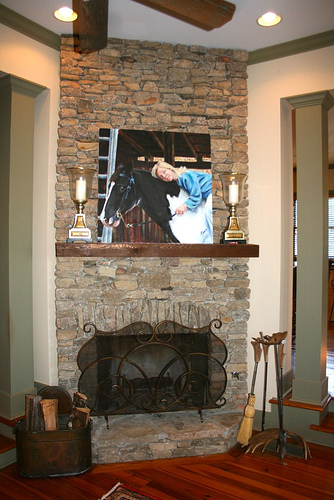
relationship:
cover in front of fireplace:
[75, 318, 229, 424] [55, 34, 260, 467]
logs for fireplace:
[24, 393, 91, 431] [55, 34, 260, 467]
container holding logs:
[13, 415, 91, 478] [24, 393, 91, 431]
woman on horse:
[151, 159, 216, 237] [98, 157, 212, 245]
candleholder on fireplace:
[221, 173, 246, 245] [55, 34, 260, 467]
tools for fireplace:
[235, 331, 313, 460] [55, 34, 260, 467]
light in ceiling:
[258, 11, 281, 27] [3, 1, 332, 55]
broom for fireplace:
[237, 342, 260, 448] [55, 34, 260, 467]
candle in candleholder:
[229, 182, 241, 205] [221, 173, 246, 245]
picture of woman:
[98, 128, 211, 246] [151, 159, 216, 237]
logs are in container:
[24, 393, 91, 431] [13, 415, 91, 478]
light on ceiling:
[52, 7, 79, 25] [3, 1, 332, 55]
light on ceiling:
[258, 11, 281, 27] [3, 1, 332, 55]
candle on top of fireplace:
[229, 182, 241, 205] [55, 34, 260, 467]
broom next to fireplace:
[237, 342, 260, 448] [55, 34, 260, 467]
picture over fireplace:
[98, 128, 211, 246] [55, 34, 260, 467]